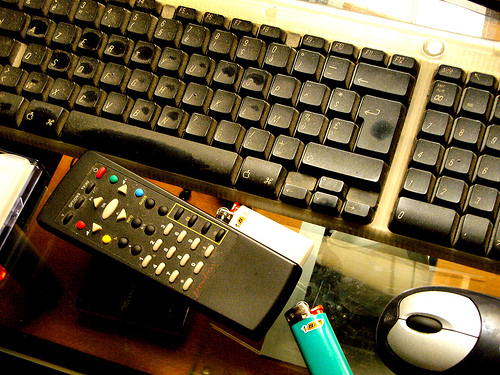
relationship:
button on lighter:
[308, 302, 325, 316] [281, 298, 360, 375]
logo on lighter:
[301, 316, 325, 333] [281, 298, 360, 375]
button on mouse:
[397, 287, 485, 340] [372, 278, 499, 375]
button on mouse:
[386, 317, 480, 371] [372, 278, 499, 375]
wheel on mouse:
[404, 311, 444, 334] [372, 278, 499, 375]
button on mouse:
[308, 302, 325, 316] [372, 278, 499, 375]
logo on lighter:
[235, 208, 252, 227] [281, 298, 360, 375]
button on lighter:
[228, 199, 242, 211] [213, 199, 318, 268]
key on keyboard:
[351, 87, 408, 163] [0, 0, 499, 278]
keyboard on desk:
[0, 0, 499, 278] [1, 1, 499, 375]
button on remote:
[90, 163, 109, 186] [29, 146, 307, 351]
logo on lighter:
[235, 208, 252, 227] [213, 199, 318, 268]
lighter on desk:
[281, 298, 360, 375] [1, 1, 499, 375]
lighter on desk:
[213, 199, 318, 268] [1, 1, 499, 375]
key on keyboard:
[261, 99, 299, 136] [0, 0, 499, 278]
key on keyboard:
[181, 51, 217, 89] [0, 0, 499, 278]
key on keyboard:
[46, 74, 84, 112] [0, 0, 499, 278]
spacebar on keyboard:
[58, 107, 246, 185] [0, 0, 499, 278]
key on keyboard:
[262, 72, 305, 108] [0, 0, 499, 278]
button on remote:
[133, 186, 146, 199] [29, 146, 307, 351]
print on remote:
[190, 257, 220, 300] [29, 146, 307, 351]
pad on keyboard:
[387, 105, 500, 262] [0, 0, 499, 278]